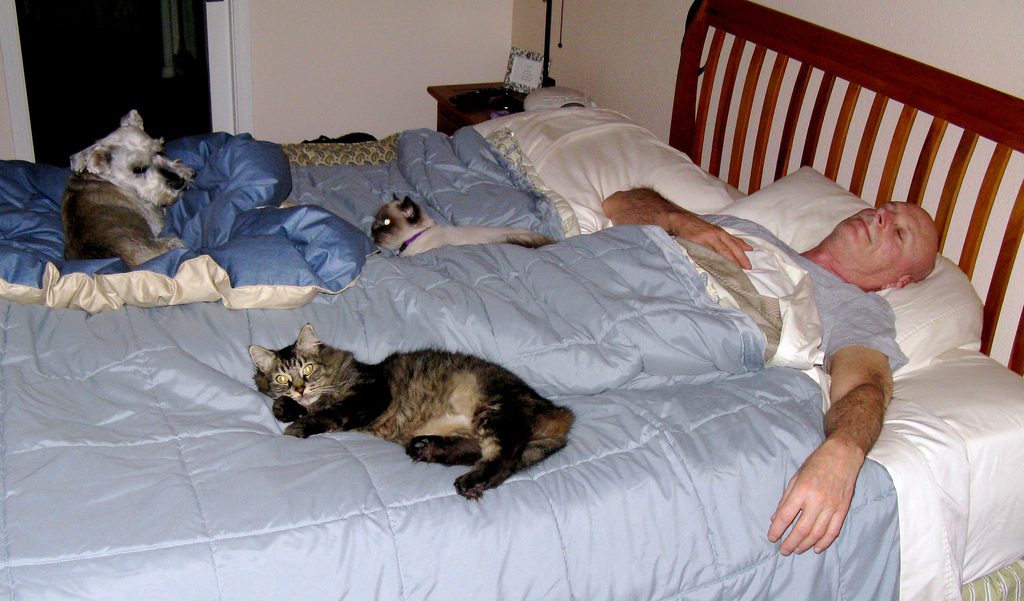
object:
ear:
[290, 321, 321, 359]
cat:
[237, 319, 582, 499]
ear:
[394, 195, 427, 224]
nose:
[870, 196, 890, 225]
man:
[586, 166, 969, 558]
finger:
[761, 472, 852, 560]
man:
[610, 124, 952, 559]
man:
[594, 180, 939, 576]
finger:
[678, 223, 752, 261]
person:
[0, 186, 939, 557]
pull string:
[525, 11, 605, 55]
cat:
[358, 189, 563, 261]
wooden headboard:
[666, 4, 1020, 382]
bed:
[46, 8, 1016, 539]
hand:
[755, 441, 879, 558]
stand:
[413, 40, 604, 140]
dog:
[58, 111, 203, 267]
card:
[492, 47, 557, 95]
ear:
[241, 342, 278, 372]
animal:
[365, 190, 555, 257]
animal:
[242, 317, 581, 502]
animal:
[53, 102, 207, 273]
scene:
[28, 100, 976, 563]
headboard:
[665, 1, 1021, 381]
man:
[607, 177, 969, 548]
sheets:
[5, 128, 824, 594]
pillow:
[465, 100, 745, 240]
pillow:
[706, 156, 983, 392]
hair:
[837, 389, 872, 439]